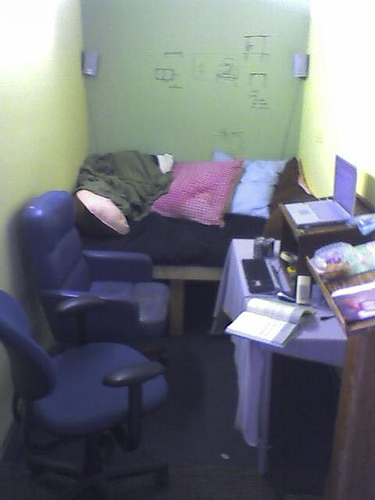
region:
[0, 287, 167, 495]
Wheeling office chair with blue cushions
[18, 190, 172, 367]
Blue office chair with wooden base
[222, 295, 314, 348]
Book with its pages open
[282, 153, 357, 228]
Laptop computer with screen open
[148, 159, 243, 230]
Pink checked toss pillow on bed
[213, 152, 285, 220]
Pale blue toss pillow on bed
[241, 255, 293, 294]
External computer keyboard with black keys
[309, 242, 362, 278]
Plastic carry-out container of baked dessert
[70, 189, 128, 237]
Cream and dark brown throw pillow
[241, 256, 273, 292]
black keyboard on table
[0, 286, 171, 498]
black and blue computer chair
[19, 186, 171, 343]
purple lounging chair by bed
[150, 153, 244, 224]
pink pillow on bed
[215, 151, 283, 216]
blue pillow on bed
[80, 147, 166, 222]
green blanket on bed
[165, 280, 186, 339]
wood leg of bed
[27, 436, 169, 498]
black lower part of chair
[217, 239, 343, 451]
purple cloth hanging from table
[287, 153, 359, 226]
computer sitting on desk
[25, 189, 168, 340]
A blue desk chair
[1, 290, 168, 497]
A blue desk chair with wheels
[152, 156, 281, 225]
Two pillows on a bed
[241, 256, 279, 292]
A keyboard on a desk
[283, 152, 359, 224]
A laptop sitting on a desk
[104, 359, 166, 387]
Black armrest of a blue desk chair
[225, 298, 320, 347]
Open book on the corner of a desk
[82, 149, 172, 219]
Discarded blanket on a bed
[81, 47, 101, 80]
Speaker hanging on a wall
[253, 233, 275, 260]
Aluminum cans in a group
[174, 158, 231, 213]
red and white check pillow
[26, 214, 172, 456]
two desk chairs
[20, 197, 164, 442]
two blue desk chairs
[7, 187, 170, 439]
two blue and black desk chairs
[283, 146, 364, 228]
open laptop computer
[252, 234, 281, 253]
multiple cans on a desk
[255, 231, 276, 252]
four cans on a desk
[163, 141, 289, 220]
blue and red pillows on a bed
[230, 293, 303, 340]
open book on a desk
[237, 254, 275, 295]
black keyboard on a desk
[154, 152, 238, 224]
The pink pillow on the bed.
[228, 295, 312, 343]
The open book on the table.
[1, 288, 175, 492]
The computer chair on the left.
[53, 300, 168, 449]
The armrests of the chair on the left.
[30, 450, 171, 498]
The feet of the chair on the left.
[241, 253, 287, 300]
The keyboard on the table.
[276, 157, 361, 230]
The laptop on the desk.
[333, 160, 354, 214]
The screen of the laptop.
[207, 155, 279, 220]
The blue pillow on the bed.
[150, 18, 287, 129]
The writing on the wall.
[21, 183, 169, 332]
dark blue waiting chair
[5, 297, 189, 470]
dark blue short backed office chair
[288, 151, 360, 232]
silver square laptop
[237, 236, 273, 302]
small black key board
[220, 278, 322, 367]
open book on desk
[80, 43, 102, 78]
silver speaker hanging on wall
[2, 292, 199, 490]
The office chair to the right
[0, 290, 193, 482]
A office chair to the right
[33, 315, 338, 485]
The black carpet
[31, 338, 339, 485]
A black carpet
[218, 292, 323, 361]
The open book